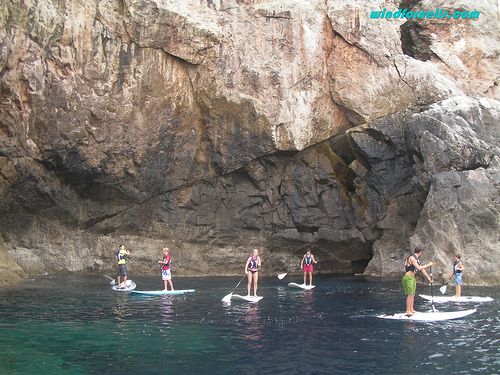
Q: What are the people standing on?
A: Surfboards.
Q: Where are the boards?
A: On the ocean.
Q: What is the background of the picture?
A: A rock cliff.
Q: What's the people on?
A: Boards.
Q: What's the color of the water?
A: Blue.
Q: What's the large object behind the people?
A: Rock wall.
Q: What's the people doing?
A: Paddle boarding.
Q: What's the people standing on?
A: Paddle boards.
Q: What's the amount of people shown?
A: Six.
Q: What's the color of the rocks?
A: Gray.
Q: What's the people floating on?
A: Water.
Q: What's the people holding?
A: Paddles.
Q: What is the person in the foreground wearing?
A: LIme shorts.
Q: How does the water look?
A: It looks peaceful.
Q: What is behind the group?
A: A rock formation.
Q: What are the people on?
A: Paddleboards.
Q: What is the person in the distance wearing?
A: Red shorts.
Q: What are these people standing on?
A: Longboards.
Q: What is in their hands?
A: Paddles.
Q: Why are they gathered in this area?
A: To paddleboard in calm water.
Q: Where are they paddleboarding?
A: In the water near a large rock.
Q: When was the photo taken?
A: During the day.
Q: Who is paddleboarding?
A: Mostly women.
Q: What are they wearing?
A: Swimwear and shorts.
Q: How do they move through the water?
A: Using the paddle.